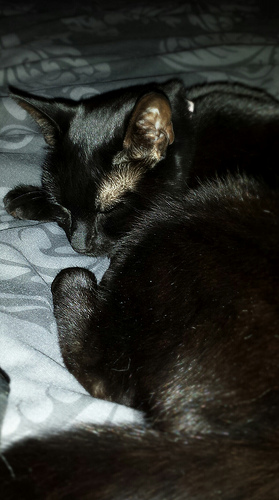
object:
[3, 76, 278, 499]
cat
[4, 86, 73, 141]
ear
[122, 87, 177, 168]
ear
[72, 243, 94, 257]
nose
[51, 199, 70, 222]
eyes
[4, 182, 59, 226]
paw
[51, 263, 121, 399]
foot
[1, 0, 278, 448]
blanket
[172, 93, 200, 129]
collar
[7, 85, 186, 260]
head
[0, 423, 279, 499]
tail